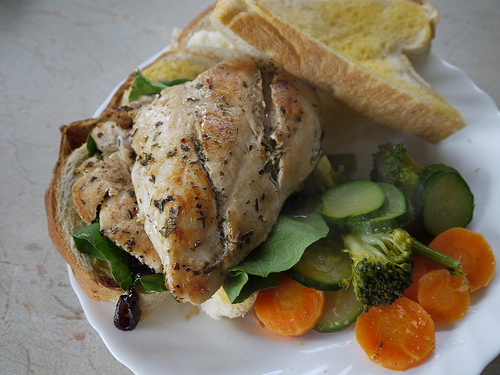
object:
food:
[42, 0, 495, 370]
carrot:
[424, 225, 496, 292]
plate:
[48, 27, 500, 375]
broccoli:
[342, 228, 416, 312]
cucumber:
[414, 172, 475, 237]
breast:
[129, 55, 325, 304]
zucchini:
[281, 230, 358, 291]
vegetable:
[222, 143, 493, 369]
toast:
[214, 0, 467, 147]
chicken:
[68, 118, 167, 278]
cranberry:
[111, 285, 141, 331]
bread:
[44, 114, 163, 305]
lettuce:
[218, 176, 329, 305]